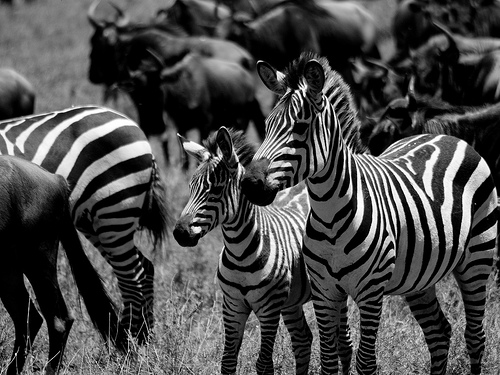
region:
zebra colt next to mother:
[173, 120, 315, 362]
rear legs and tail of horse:
[4, 148, 131, 371]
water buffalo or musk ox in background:
[79, 1, 257, 160]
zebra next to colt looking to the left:
[255, 58, 499, 369]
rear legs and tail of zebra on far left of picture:
[3, 106, 176, 296]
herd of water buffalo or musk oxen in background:
[75, 2, 492, 164]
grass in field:
[5, 137, 495, 373]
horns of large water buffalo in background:
[81, 5, 142, 25]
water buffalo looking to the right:
[371, 76, 454, 123]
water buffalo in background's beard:
[98, 91, 119, 110]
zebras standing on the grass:
[2, 51, 493, 373]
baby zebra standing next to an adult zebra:
[167, 49, 497, 374]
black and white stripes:
[387, 132, 499, 227]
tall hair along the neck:
[287, 52, 378, 149]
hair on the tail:
[122, 153, 188, 257]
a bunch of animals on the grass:
[1, 1, 496, 373]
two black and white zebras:
[158, 53, 499, 370]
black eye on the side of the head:
[289, 120, 315, 140]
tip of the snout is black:
[171, 223, 201, 250]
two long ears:
[172, 121, 237, 168]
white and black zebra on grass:
[278, 66, 498, 321]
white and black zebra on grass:
[165, 148, 296, 351]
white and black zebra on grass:
[2, 100, 149, 328]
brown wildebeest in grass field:
[122, 40, 250, 141]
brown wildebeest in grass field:
[80, 14, 116, 68]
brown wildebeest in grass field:
[419, 28, 499, 108]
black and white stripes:
[340, 176, 461, 251]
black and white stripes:
[59, 119, 134, 188]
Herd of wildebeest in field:
[71, 5, 497, 159]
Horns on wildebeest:
[79, 4, 136, 28]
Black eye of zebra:
[287, 120, 312, 139]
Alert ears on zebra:
[249, 58, 329, 93]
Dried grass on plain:
[5, 10, 492, 370]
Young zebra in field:
[174, 126, 319, 373]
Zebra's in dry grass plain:
[4, 51, 496, 368]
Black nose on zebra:
[239, 164, 278, 209]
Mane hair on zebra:
[278, 51, 369, 160]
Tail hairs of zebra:
[144, 158, 172, 255]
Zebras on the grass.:
[172, 50, 499, 373]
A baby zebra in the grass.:
[171, 125, 355, 373]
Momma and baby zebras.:
[171, 48, 497, 374]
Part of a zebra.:
[2, 103, 174, 350]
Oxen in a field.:
[83, 0, 498, 190]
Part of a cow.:
[1, 154, 131, 374]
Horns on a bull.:
[84, 3, 131, 29]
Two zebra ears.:
[253, 56, 325, 96]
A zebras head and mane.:
[238, 50, 372, 207]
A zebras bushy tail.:
[134, 153, 178, 265]